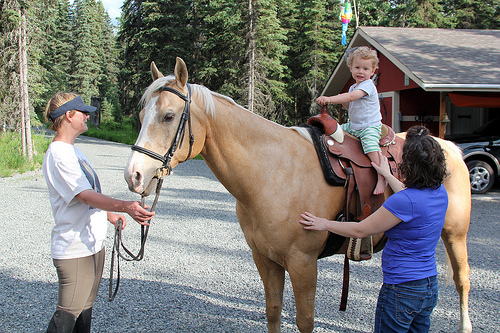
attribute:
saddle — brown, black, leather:
[310, 101, 411, 218]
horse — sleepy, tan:
[125, 56, 473, 332]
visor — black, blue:
[48, 94, 97, 120]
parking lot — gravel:
[0, 167, 499, 332]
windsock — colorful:
[337, 1, 354, 46]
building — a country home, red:
[316, 26, 500, 147]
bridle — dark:
[131, 75, 194, 177]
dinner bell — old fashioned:
[442, 113, 451, 135]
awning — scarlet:
[450, 91, 500, 107]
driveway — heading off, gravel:
[36, 124, 133, 158]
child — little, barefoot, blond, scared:
[314, 45, 393, 194]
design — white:
[130, 95, 160, 165]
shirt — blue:
[381, 183, 449, 285]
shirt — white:
[44, 143, 111, 254]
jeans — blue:
[374, 277, 438, 332]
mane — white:
[141, 73, 218, 121]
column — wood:
[438, 91, 448, 139]